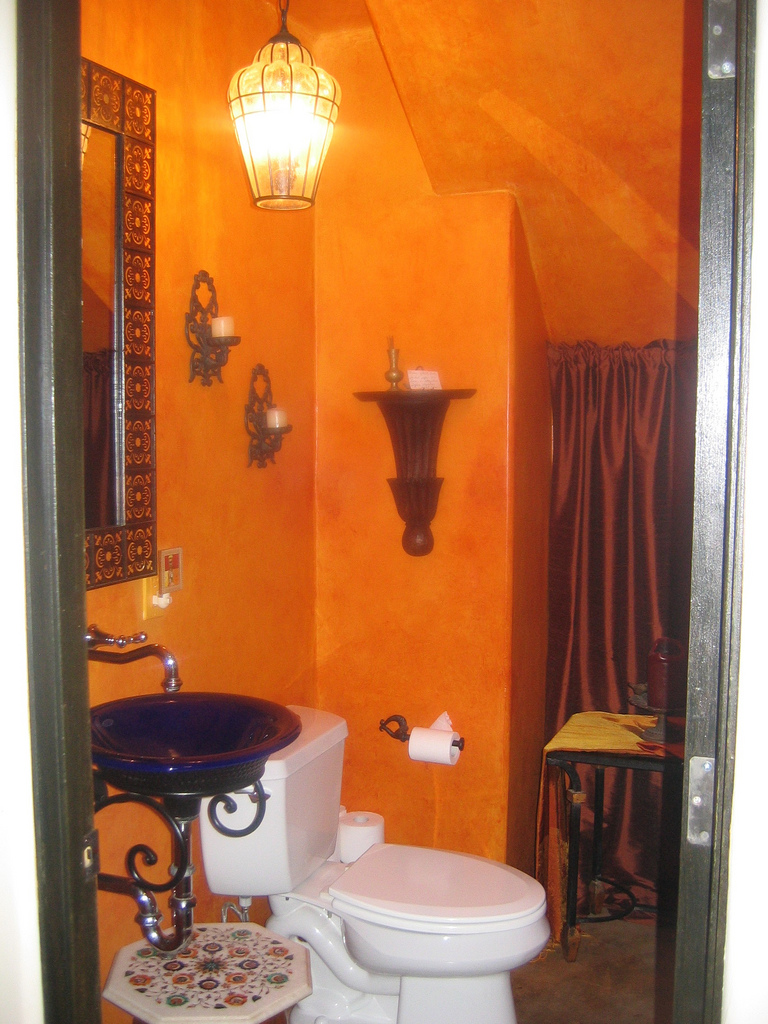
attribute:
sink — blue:
[77, 674, 310, 877]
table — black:
[536, 710, 682, 948]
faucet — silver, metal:
[83, 616, 188, 702]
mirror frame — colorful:
[76, 67, 164, 593]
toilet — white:
[229, 724, 544, 966]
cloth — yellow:
[564, 661, 657, 782]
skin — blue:
[100, 675, 294, 813]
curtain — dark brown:
[526, 330, 690, 958]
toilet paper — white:
[401, 721, 465, 771]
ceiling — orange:
[281, 0, 697, 349]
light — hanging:
[219, 3, 347, 220]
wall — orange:
[116, 14, 560, 857]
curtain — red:
[546, 327, 691, 930]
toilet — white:
[188, 696, 559, 1019]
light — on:
[213, 9, 352, 224]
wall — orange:
[105, 4, 317, 1020]